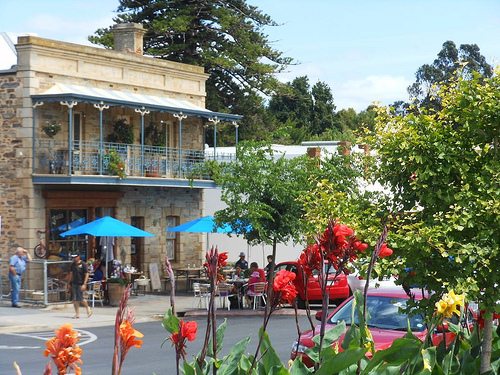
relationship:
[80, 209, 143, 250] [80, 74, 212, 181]
umbrella in front of building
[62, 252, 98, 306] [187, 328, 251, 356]
man on road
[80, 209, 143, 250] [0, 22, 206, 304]
umbrella outside of building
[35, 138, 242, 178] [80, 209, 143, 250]
railing over umbrella